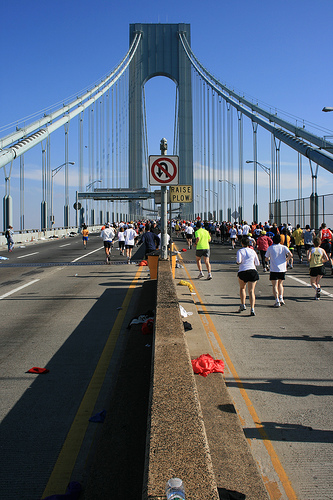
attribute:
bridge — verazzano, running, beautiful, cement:
[25, 115, 297, 500]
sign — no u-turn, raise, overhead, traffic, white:
[141, 139, 199, 201]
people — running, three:
[156, 194, 309, 301]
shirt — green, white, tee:
[181, 214, 224, 259]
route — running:
[42, 188, 191, 373]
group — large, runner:
[165, 181, 304, 339]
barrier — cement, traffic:
[111, 267, 221, 471]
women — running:
[221, 225, 313, 343]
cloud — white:
[86, 141, 118, 171]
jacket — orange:
[246, 223, 293, 253]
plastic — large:
[192, 342, 232, 375]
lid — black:
[129, 228, 152, 253]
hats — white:
[92, 222, 136, 234]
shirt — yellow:
[196, 227, 208, 251]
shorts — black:
[197, 246, 209, 258]